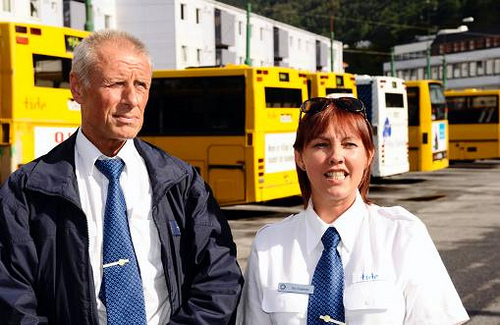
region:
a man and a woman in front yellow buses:
[1, 17, 476, 322]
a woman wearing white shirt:
[232, 85, 472, 320]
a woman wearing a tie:
[226, 88, 479, 323]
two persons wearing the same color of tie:
[6, 21, 463, 321]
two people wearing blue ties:
[5, 20, 470, 322]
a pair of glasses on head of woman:
[270, 75, 386, 225]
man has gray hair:
[36, 15, 171, 180]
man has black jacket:
[5, 20, 246, 316]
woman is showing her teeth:
[256, 75, 401, 236]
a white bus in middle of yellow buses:
[368, 70, 415, 183]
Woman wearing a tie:
[259, 80, 401, 324]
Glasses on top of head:
[288, 87, 386, 123]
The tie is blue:
[308, 200, 339, 320]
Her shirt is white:
[252, 201, 435, 322]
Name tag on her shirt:
[262, 272, 323, 302]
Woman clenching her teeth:
[308, 127, 373, 190]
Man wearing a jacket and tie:
[12, 12, 252, 321]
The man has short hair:
[60, 27, 180, 157]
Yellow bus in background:
[156, 37, 318, 220]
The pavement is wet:
[388, 160, 491, 295]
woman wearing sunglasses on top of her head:
[287, 91, 385, 216]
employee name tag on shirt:
[278, 277, 316, 297]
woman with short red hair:
[289, 86, 386, 213]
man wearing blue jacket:
[11, 27, 238, 321]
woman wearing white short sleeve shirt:
[236, 84, 472, 324]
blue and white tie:
[308, 227, 348, 315]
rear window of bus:
[260, 75, 307, 109]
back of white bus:
[367, 70, 418, 177]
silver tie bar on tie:
[98, 256, 134, 273]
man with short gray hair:
[71, 25, 154, 154]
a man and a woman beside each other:
[6, 25, 476, 323]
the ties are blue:
[83, 156, 356, 323]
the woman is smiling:
[282, 84, 388, 213]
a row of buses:
[6, 13, 470, 211]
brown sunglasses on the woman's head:
[276, 91, 400, 216]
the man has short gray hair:
[53, 25, 163, 155]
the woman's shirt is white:
[236, 190, 469, 324]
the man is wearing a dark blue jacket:
[2, 131, 247, 323]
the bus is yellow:
[144, 52, 310, 211]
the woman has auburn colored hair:
[286, 85, 385, 205]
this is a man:
[63, 45, 180, 323]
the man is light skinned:
[89, 87, 121, 127]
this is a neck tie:
[106, 198, 143, 302]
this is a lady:
[285, 107, 379, 272]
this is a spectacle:
[306, 97, 366, 110]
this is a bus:
[196, 85, 272, 154]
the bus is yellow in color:
[221, 143, 255, 169]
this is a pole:
[243, 9, 253, 55]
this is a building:
[147, 14, 270, 66]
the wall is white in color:
[140, 10, 170, 30]